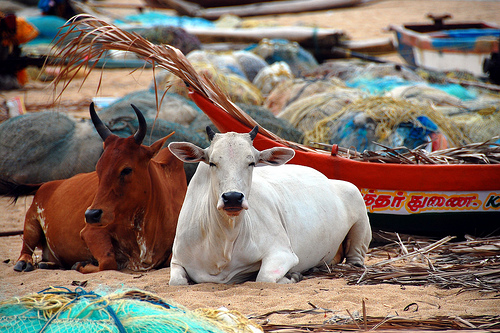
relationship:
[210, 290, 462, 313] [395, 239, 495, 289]
sand with sticks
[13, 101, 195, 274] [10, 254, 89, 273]
brown cow with black hooves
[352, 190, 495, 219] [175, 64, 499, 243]
lettering on boat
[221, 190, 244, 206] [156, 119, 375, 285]
black nose of bull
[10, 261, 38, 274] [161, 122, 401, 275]
black hooves of bull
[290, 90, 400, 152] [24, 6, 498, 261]
nets on boat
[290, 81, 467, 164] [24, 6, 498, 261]
buoys on boat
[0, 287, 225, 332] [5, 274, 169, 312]
buoys under netting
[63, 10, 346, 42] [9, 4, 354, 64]
pole behind boat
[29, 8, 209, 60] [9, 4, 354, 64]
fabric behind boat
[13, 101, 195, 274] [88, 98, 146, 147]
brown cow has horns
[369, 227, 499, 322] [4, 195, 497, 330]
sticks on ground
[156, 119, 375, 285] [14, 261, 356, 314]
bull on ground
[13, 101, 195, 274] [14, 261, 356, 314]
brown cow on ground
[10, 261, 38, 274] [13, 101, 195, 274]
black hooves of brown cow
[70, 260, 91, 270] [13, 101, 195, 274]
hoof of brown cow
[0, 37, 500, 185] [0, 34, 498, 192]
bags wrapped in net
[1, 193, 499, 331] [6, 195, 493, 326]
twigs on sand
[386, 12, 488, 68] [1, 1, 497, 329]
boat on beach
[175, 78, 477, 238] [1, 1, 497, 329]
boat on beach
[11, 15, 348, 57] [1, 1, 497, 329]
boat on beach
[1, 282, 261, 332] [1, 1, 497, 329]
fishing equipment on beach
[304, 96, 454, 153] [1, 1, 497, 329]
fishing equipment on beach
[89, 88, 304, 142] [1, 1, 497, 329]
fishing equipment on beach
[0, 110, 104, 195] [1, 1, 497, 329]
fishing equipment on beach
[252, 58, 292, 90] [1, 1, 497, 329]
fishing equipment on beach